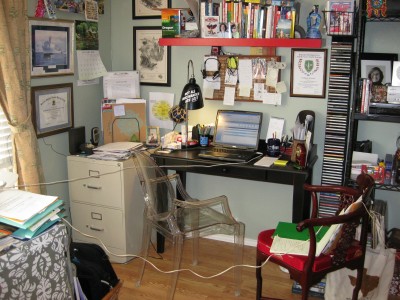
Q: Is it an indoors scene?
A: Yes, it is indoors.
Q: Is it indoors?
A: Yes, it is indoors.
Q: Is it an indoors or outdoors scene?
A: It is indoors.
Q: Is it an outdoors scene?
A: No, it is indoors.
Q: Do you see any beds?
A: No, there are no beds.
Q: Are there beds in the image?
A: No, there are no beds.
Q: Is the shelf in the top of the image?
A: Yes, the shelf is in the top of the image.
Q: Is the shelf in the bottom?
A: No, the shelf is in the top of the image.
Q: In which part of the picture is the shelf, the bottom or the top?
A: The shelf is in the top of the image.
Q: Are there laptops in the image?
A: Yes, there is a laptop.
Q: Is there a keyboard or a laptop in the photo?
A: Yes, there is a laptop.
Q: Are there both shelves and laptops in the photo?
A: Yes, there are both a laptop and a shelf.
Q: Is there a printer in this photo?
A: No, there are no printers.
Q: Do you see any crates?
A: No, there are no crates.